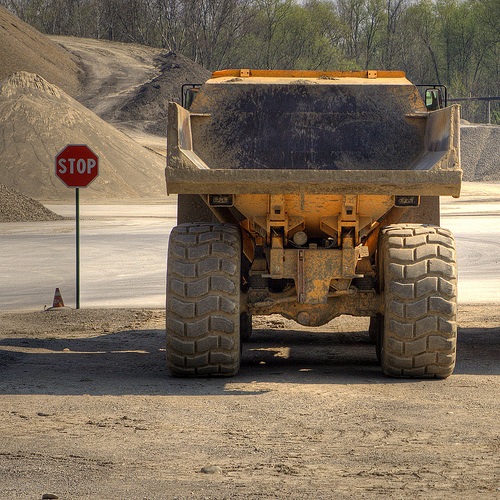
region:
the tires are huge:
[146, 228, 256, 368]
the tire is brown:
[163, 225, 248, 372]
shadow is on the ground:
[34, 330, 134, 412]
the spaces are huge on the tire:
[178, 270, 227, 289]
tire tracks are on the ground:
[268, 417, 394, 483]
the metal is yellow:
[270, 255, 355, 321]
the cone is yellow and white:
[43, 287, 73, 309]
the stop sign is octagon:
[46, 145, 113, 191]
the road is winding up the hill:
[46, 31, 186, 130]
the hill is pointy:
[14, 70, 171, 197]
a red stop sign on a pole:
[50, 134, 107, 192]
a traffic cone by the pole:
[47, 277, 71, 319]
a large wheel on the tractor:
[157, 214, 243, 381]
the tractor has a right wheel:
[377, 219, 460, 386]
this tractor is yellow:
[161, 66, 447, 368]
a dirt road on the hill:
[51, 18, 153, 125]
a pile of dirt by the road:
[0, 60, 182, 201]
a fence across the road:
[440, 92, 497, 127]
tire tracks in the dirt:
[41, 409, 481, 497]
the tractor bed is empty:
[156, 77, 465, 197]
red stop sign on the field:
[54, 143, 98, 188]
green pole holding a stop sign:
[76, 186, 81, 310]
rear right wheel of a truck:
[381, 222, 456, 377]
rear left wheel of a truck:
[166, 223, 241, 374]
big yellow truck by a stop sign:
[166, 68, 460, 380]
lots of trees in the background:
[4, 0, 499, 120]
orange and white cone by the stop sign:
[52, 287, 64, 307]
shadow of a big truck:
[0, 329, 376, 397]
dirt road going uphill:
[40, 33, 162, 125]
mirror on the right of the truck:
[425, 88, 442, 110]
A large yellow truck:
[153, 64, 468, 379]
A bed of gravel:
[1, 300, 496, 497]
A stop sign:
[51, 141, 100, 190]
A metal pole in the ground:
[71, 188, 81, 308]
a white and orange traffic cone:
[50, 288, 68, 308]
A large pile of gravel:
[0, 69, 170, 198]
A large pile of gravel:
[0, 6, 212, 137]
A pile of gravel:
[2, 183, 57, 222]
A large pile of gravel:
[459, 119, 499, 182]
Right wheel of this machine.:
[374, 229, 456, 381]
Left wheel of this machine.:
[159, 218, 247, 376]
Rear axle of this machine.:
[239, 287, 390, 323]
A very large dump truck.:
[164, 60, 465, 378]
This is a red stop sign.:
[46, 137, 112, 199]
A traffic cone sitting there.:
[41, 280, 74, 325]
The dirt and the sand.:
[61, 395, 448, 475]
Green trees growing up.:
[286, 9, 467, 59]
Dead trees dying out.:
[19, 6, 241, 68]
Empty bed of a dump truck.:
[201, 88, 433, 163]